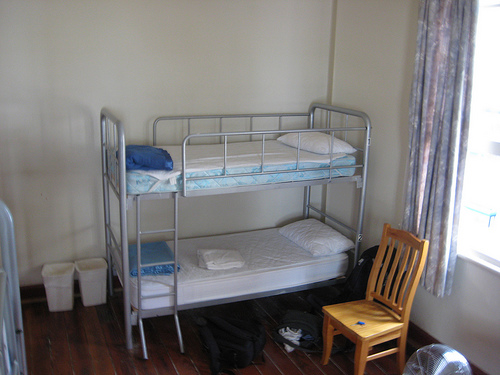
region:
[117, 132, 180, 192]
blue blanket laying on bed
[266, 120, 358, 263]
pillows laying on beds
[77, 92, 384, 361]
silver bunk beds against the wall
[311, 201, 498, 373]
wooden chair sitting near window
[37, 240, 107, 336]
two small waste baskets sitting on floor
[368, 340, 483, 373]
metal fan sitting in floor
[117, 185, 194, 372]
metal ladder on bunk beds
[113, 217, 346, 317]
mattress on lower bunk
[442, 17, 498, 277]
window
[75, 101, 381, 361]
silver bunk beds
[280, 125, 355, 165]
a white pillow on the bed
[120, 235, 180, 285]
folded blue blanket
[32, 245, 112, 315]
two white garbage cans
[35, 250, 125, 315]
two small garbage cans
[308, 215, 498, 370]
a wood chair in front of the window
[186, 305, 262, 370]
a black back pack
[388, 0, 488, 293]
an open curtain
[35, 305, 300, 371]
a dark wood floor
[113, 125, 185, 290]
two folded blankets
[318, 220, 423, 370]
the chair is brown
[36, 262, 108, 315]
the trash cans are white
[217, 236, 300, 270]
the matresses are white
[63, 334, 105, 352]
the floor is brown wood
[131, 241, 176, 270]
the bedsheet is blue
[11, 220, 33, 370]
the bed is metallic grey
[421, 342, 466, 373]
the fun is on the ground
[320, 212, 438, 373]
a brown chair in a room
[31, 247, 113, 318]
two white trash cans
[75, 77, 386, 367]
silver bunkbeds in a room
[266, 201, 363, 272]
a white pillow on a bed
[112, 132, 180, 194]
a folded blue blanket on a bed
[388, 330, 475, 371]
the top half of a fan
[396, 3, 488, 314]
curtains for a window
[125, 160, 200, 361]
a ladder on the bunkbed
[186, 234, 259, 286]
a folded white sheet for a bed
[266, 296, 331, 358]
a black bag on a wooden floor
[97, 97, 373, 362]
the bed is a bunk bed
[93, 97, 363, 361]
the bed is small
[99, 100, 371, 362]
the bed is metal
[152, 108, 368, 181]
the top has guard rails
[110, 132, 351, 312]
the bed has white sheets on the mattresses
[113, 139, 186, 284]
the bed has blue blankets folded at the foot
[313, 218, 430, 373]
the chair is small and brown and it is made of wood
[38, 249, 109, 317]
there are two white trashcans at the foot of the bed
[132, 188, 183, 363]
the bed has a ladder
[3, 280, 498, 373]
the floor is dark hard wood